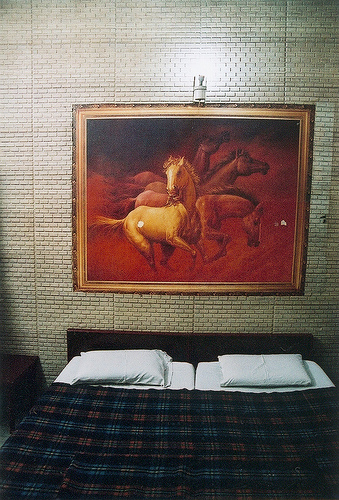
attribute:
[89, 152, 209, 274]
horse — tan